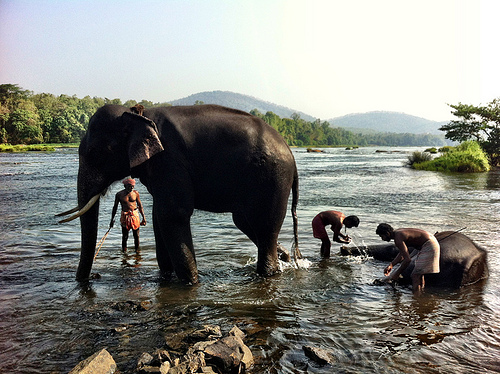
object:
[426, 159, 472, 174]
wall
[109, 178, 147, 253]
man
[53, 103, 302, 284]
elephant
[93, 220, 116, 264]
stick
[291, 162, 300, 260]
tail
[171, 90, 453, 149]
mountains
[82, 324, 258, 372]
rocks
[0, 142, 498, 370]
water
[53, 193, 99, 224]
trunk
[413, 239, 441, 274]
cloth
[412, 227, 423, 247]
waist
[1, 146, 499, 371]
river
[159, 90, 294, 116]
peak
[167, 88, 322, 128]
hill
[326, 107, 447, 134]
hill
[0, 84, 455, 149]
trees lines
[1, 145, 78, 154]
riverbank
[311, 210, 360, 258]
man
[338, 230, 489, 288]
elephant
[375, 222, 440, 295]
man